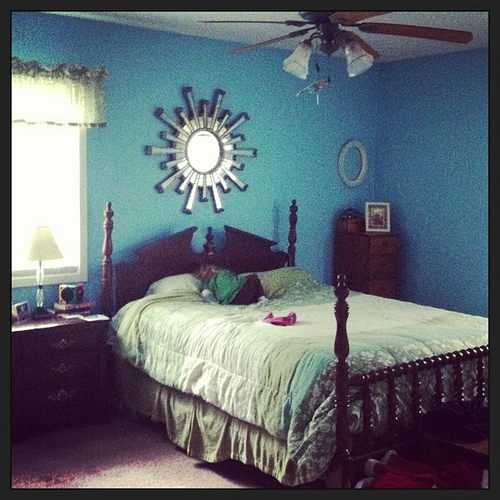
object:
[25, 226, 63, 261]
lamp shade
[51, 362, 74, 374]
handle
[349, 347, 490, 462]
railing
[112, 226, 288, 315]
headboard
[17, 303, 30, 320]
picture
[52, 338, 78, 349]
handle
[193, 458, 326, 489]
shadow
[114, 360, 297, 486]
bed skirt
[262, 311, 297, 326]
clothing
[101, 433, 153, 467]
floor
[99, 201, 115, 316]
post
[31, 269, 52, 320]
base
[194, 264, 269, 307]
child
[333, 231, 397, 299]
cabinet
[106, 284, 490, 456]
bedspread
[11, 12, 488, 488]
bedroom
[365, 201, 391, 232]
frame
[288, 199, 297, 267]
post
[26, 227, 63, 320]
lamp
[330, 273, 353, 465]
post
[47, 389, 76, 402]
handle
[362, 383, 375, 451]
post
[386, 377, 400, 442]
post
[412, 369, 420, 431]
post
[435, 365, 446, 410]
post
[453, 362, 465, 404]
post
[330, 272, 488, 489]
footboard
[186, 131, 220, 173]
mirror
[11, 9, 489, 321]
wall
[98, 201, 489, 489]
bed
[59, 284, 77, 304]
clock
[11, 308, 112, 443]
night stand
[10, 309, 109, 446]
dresser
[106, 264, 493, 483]
comforter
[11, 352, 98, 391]
drawer